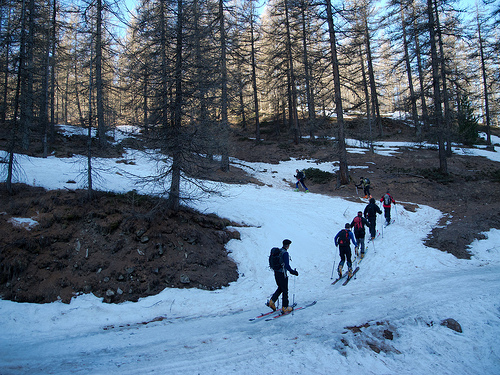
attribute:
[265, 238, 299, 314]
person — here, walking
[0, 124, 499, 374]
snow — white, here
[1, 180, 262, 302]
dirt — brown, present, here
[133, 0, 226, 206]
tree — bare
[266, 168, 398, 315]
people — walking, here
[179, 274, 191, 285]
stone — here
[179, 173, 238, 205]
branch — here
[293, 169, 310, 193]
person — skiing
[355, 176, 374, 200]
person — skiing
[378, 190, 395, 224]
person — skiing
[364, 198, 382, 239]
person — skiing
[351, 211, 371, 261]
person — skiing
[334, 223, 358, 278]
person — skiing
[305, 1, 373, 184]
tree — bare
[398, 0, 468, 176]
tree — bare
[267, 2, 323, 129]
tree — bare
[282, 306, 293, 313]
boot — brown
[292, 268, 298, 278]
glove — black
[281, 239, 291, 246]
hat — black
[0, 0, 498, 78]
sky — blue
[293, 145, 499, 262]
dirt — here